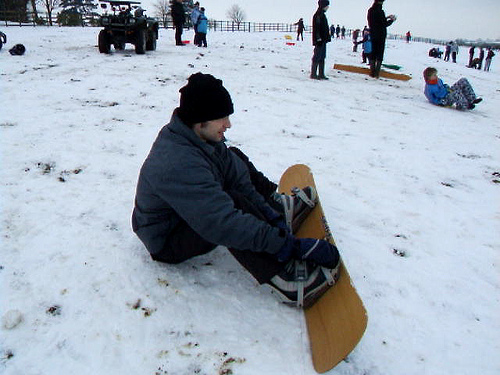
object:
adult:
[366, 0, 398, 81]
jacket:
[130, 105, 292, 259]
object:
[333, 62, 412, 82]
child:
[422, 65, 484, 112]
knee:
[228, 145, 246, 166]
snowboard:
[275, 162, 369, 373]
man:
[131, 70, 340, 310]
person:
[306, 0, 333, 81]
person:
[169, 0, 188, 47]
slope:
[0, 24, 495, 375]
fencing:
[0, 9, 313, 32]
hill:
[1, 22, 499, 374]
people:
[480, 47, 495, 71]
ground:
[0, 24, 500, 374]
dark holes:
[440, 180, 455, 190]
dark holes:
[390, 247, 406, 260]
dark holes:
[132, 298, 142, 310]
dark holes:
[44, 305, 63, 319]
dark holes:
[38, 162, 56, 176]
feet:
[269, 252, 343, 310]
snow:
[0, 24, 500, 374]